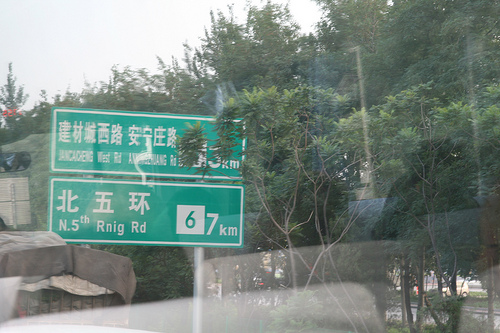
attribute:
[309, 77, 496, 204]
leaves — green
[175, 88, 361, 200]
leaves — green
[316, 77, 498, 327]
tree — brown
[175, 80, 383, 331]
tree — brown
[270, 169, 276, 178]
leaf — green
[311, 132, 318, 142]
leaf — green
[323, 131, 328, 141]
leaf — green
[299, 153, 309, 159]
leaf — green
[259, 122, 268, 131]
leaf — green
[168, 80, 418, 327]
tree — brown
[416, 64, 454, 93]
leaves — green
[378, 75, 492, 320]
tree — brown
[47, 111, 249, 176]
sign — green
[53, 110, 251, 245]
highway sign — green, white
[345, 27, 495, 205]
leaves — green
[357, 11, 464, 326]
tree — brown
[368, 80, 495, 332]
tree — brown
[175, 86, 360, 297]
tree — brown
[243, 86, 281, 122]
leaves — green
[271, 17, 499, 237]
tree — brown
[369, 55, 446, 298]
tree — brown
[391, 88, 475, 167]
leaves — green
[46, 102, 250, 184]
sign — green, green and white, white and green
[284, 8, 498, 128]
leaves — green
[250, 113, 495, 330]
tree — brown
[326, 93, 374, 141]
leaves — green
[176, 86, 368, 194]
leaves — green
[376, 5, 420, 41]
leaves — green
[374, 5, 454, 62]
tree — brown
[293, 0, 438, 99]
tree — brown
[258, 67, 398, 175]
leaves — green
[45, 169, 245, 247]
sign — white and green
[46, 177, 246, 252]
sign — green, green and white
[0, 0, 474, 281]
leaves — green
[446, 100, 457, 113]
leaf — green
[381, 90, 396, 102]
leaf — green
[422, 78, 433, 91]
leaf — green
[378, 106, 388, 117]
leaf — green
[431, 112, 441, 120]
leaf — green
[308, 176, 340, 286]
tree — brown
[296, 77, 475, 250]
tree — brown